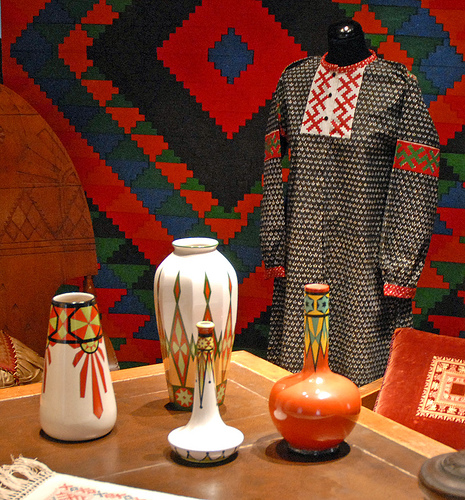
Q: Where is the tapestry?
A: Hang on wall in the background.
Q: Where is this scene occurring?
A: Museum.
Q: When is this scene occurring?
A: Mid afternoon.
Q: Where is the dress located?
A: Behind table on right.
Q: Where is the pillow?
A: On chair to the right of table.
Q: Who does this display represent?
A: American Indians.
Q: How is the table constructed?
A: With wood.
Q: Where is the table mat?
A: On table front left.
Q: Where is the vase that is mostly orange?
A: On table on the right.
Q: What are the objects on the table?
A: Vases.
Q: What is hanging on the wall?
A: A woven rug with red, blue, black and green designs.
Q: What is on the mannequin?
A: A black and white robe with red, white, and green designs.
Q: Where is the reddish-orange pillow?
A: Next to the table.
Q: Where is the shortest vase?
A: In front.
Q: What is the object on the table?
A: A vase.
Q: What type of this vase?
A: American Indian.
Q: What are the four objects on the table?
A: Vases.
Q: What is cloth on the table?
A: A blanket.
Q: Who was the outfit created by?
A: American Indians.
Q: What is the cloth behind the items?
A: An Indian blanket.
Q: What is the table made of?
A: Wood.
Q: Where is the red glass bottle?
A: On the table.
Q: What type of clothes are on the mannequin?
A: A grey suit.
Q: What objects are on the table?
A: Vases.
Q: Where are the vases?
A: On the table.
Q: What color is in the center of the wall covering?
A: Blue.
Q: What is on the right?
A: Pillow.